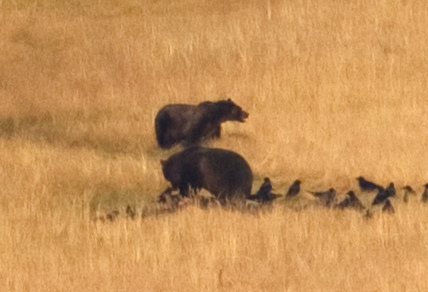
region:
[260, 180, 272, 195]
small bird in field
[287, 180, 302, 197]
small bird in field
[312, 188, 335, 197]
small bird in field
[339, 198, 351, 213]
small bird in field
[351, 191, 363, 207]
small bird in field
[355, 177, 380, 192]
small bird in field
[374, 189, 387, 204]
small bird in field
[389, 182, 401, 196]
small bird in field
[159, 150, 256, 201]
Brown bear walking through field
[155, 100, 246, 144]
Brown bear walking through field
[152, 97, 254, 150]
Black bear standing in field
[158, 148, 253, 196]
Black bear standing in field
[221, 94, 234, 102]
Ear of black bear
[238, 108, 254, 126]
Mouth of black bear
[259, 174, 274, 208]
Small bird near bear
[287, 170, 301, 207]
Small bird near bear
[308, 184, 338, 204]
Small bear near bear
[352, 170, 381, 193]
Small bird near bear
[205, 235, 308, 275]
Heavy brown grass near bears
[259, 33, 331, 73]
Heavy brown grass near bears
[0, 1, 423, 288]
bears and birds in a field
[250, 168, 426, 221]
black birds in a brown tall grass field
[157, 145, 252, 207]
one of two bears in a brown grassy field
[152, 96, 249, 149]
one of two bears in a brown grassy field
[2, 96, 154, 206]
green areas in a brown grassy field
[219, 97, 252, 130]
head of a bear in a brown grassy field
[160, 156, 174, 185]
head of a bear in a brown grassy field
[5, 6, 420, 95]
long brown grass in a field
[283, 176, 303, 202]
a bird in a brown grassy field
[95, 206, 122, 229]
bird behind grass in a brown grassy field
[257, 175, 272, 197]
black bird on ground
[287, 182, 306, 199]
black bird on ground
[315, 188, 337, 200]
black bird on ground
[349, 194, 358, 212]
black bird on ground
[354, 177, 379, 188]
black bird on ground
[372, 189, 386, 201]
black bird on ground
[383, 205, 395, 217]
black bird on ground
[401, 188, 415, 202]
black bird on ground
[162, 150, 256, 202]
brown bear in field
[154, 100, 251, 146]
brown bear in field